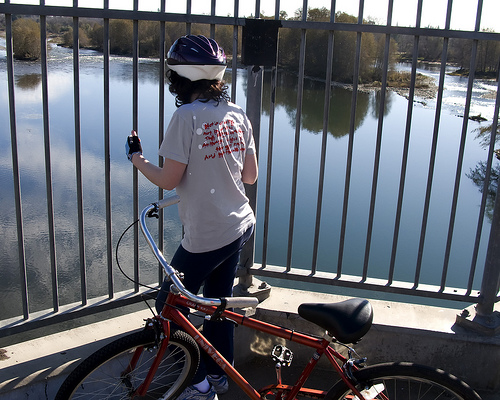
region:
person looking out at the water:
[88, 42, 461, 399]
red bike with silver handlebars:
[33, 197, 483, 398]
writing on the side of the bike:
[189, 323, 231, 375]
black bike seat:
[283, 286, 393, 344]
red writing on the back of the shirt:
[184, 113, 251, 167]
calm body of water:
[6, 71, 446, 300]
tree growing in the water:
[9, 16, 51, 68]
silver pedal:
[268, 343, 294, 365]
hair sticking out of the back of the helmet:
[171, 69, 228, 109]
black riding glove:
[117, 122, 144, 164]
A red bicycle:
[53, 194, 476, 399]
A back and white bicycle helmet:
[157, 30, 230, 80]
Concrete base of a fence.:
[2, 271, 499, 393]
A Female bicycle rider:
[127, 31, 261, 397]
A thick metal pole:
[456, 174, 498, 329]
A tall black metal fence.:
[1, 18, 493, 298]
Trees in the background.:
[0, 17, 497, 79]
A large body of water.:
[1, 50, 497, 282]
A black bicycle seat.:
[291, 291, 377, 348]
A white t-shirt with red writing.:
[157, 96, 254, 251]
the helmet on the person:
[165, 32, 221, 79]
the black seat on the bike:
[296, 297, 371, 341]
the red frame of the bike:
[153, 286, 351, 396]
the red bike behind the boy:
[56, 192, 482, 398]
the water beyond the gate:
[13, 77, 119, 268]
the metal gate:
[8, 2, 496, 265]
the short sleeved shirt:
[156, 105, 256, 243]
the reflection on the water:
[262, 73, 393, 143]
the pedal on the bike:
[271, 341, 293, 367]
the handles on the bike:
[137, 192, 255, 308]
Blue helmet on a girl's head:
[165, 35, 229, 65]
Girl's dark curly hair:
[165, 76, 232, 103]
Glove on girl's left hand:
[124, 129, 144, 161]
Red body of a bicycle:
[165, 300, 327, 392]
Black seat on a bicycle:
[298, 297, 377, 337]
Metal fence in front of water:
[43, 2, 248, 294]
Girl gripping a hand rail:
[119, 129, 263, 188]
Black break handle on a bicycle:
[201, 310, 238, 327]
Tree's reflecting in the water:
[256, 70, 379, 142]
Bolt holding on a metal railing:
[459, 308, 470, 319]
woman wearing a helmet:
[144, 32, 251, 96]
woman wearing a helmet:
[131, 12, 218, 90]